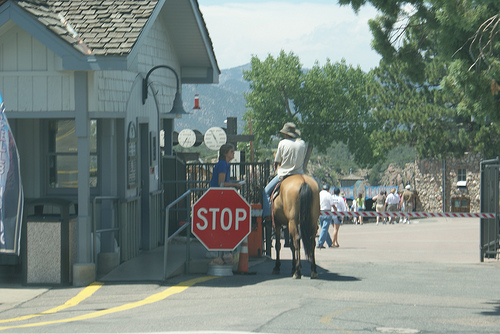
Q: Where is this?
A: This is at the road.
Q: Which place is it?
A: It is a road.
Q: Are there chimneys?
A: No, there are no chimneys.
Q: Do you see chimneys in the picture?
A: No, there are no chimneys.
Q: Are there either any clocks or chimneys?
A: No, there are no chimneys or clocks.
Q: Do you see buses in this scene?
A: No, there are no buses.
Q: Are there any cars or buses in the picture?
A: No, there are no buses or cars.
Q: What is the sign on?
A: The sign is on the pole.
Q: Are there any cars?
A: No, there are no cars.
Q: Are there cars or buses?
A: No, there are no cars or buses.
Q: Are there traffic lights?
A: No, there are no traffic lights.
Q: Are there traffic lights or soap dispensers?
A: No, there are no traffic lights or soap dispensers.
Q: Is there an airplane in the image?
A: No, there are no airplanes.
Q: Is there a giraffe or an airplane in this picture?
A: No, there are no airplanes or giraffes.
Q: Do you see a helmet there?
A: No, there are no helmets.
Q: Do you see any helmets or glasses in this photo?
A: No, there are no helmets or glasses.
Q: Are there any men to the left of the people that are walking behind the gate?
A: Yes, there is a man to the left of the people.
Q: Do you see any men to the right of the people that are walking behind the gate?
A: No, the man is to the left of the people.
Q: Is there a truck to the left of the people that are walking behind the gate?
A: No, there is a man to the left of the people.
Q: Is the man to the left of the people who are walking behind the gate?
A: Yes, the man is to the left of the people.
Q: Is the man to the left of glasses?
A: No, the man is to the left of the people.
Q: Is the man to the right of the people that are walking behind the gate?
A: No, the man is to the left of the people.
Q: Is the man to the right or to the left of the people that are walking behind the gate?
A: The man is to the left of the people.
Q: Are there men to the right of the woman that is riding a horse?
A: Yes, there is a man to the right of the woman.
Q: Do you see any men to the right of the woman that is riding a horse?
A: Yes, there is a man to the right of the woman.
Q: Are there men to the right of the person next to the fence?
A: Yes, there is a man to the right of the woman.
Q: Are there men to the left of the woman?
A: No, the man is to the right of the woman.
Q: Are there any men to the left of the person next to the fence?
A: No, the man is to the right of the woman.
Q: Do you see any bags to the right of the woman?
A: No, there is a man to the right of the woman.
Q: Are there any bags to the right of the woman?
A: No, there is a man to the right of the woman.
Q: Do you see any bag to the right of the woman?
A: No, there is a man to the right of the woman.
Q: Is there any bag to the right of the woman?
A: No, there is a man to the right of the woman.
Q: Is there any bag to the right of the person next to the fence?
A: No, there is a man to the right of the woman.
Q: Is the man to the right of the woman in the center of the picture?
A: Yes, the man is to the right of the woman.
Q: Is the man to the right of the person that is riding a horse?
A: Yes, the man is to the right of the woman.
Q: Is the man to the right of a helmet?
A: No, the man is to the right of the woman.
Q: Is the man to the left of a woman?
A: No, the man is to the right of a woman.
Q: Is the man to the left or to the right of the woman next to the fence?
A: The man is to the right of the woman.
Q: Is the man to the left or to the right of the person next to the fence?
A: The man is to the right of the woman.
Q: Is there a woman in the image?
A: Yes, there is a woman.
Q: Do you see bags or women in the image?
A: Yes, there is a woman.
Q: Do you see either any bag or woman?
A: Yes, there is a woman.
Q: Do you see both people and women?
A: Yes, there are both a woman and a person.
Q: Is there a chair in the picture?
A: No, there are no chairs.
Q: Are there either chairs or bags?
A: No, there are no chairs or bags.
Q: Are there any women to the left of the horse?
A: Yes, there is a woman to the left of the horse.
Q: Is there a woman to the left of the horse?
A: Yes, there is a woman to the left of the horse.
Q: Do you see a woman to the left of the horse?
A: Yes, there is a woman to the left of the horse.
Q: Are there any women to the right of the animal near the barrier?
A: No, the woman is to the left of the horse.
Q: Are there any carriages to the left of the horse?
A: No, there is a woman to the left of the horse.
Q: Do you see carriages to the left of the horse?
A: No, there is a woman to the left of the horse.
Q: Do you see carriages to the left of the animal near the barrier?
A: No, there is a woman to the left of the horse.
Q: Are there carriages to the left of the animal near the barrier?
A: No, there is a woman to the left of the horse.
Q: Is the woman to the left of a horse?
A: Yes, the woman is to the left of a horse.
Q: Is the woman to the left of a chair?
A: No, the woman is to the left of a horse.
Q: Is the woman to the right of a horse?
A: No, the woman is to the left of a horse.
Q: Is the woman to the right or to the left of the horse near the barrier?
A: The woman is to the left of the horse.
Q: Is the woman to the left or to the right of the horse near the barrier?
A: The woman is to the left of the horse.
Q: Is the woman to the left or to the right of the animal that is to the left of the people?
A: The woman is to the left of the horse.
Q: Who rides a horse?
A: The woman rides a horse.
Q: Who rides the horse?
A: The woman rides a horse.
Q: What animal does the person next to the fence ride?
A: The woman rides a horse.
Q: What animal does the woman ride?
A: The woman rides a horse.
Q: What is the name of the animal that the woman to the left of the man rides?
A: The animal is a horse.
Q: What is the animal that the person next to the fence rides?
A: The animal is a horse.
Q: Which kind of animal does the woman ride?
A: The woman rides a horse.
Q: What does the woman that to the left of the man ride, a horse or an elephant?
A: The woman rides a horse.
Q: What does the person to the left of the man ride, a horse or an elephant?
A: The woman rides a horse.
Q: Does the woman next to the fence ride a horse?
A: Yes, the woman rides a horse.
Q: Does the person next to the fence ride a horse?
A: Yes, the woman rides a horse.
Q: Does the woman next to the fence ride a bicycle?
A: No, the woman rides a horse.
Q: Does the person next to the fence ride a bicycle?
A: No, the woman rides a horse.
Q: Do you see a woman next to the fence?
A: Yes, there is a woman next to the fence.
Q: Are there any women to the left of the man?
A: Yes, there is a woman to the left of the man.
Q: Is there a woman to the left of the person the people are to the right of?
A: Yes, there is a woman to the left of the man.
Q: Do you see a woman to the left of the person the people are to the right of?
A: Yes, there is a woman to the left of the man.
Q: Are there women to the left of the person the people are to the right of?
A: Yes, there is a woman to the left of the man.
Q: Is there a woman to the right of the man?
A: No, the woman is to the left of the man.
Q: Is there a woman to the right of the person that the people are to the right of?
A: No, the woman is to the left of the man.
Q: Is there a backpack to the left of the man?
A: No, there is a woman to the left of the man.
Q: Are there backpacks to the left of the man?
A: No, there is a woman to the left of the man.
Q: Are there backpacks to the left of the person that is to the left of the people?
A: No, there is a woman to the left of the man.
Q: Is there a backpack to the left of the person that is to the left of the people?
A: No, there is a woman to the left of the man.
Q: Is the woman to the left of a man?
A: Yes, the woman is to the left of a man.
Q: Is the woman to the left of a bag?
A: No, the woman is to the left of a man.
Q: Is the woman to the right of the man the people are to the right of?
A: No, the woman is to the left of the man.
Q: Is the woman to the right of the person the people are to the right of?
A: No, the woman is to the left of the man.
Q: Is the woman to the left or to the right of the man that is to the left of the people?
A: The woman is to the left of the man.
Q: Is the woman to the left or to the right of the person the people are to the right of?
A: The woman is to the left of the man.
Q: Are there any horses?
A: Yes, there is a horse.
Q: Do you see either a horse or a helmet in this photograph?
A: Yes, there is a horse.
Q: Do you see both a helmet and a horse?
A: No, there is a horse but no helmets.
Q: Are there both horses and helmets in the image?
A: No, there is a horse but no helmets.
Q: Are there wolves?
A: No, there are no wolves.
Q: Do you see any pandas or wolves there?
A: No, there are no wolves or pandas.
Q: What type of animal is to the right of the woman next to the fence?
A: The animal is a horse.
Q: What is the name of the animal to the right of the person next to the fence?
A: The animal is a horse.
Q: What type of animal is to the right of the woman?
A: The animal is a horse.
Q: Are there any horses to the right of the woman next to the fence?
A: Yes, there is a horse to the right of the woman.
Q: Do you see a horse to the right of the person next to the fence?
A: Yes, there is a horse to the right of the woman.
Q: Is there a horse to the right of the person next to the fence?
A: Yes, there is a horse to the right of the woman.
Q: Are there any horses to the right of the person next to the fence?
A: Yes, there is a horse to the right of the woman.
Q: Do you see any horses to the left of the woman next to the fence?
A: No, the horse is to the right of the woman.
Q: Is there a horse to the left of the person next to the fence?
A: No, the horse is to the right of the woman.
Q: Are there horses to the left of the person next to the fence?
A: No, the horse is to the right of the woman.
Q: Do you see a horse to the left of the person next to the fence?
A: No, the horse is to the right of the woman.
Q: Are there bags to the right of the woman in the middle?
A: No, there is a horse to the right of the woman.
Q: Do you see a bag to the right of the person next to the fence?
A: No, there is a horse to the right of the woman.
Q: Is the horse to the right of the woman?
A: Yes, the horse is to the right of the woman.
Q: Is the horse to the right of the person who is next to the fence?
A: Yes, the horse is to the right of the woman.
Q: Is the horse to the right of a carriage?
A: No, the horse is to the right of the woman.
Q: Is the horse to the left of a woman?
A: No, the horse is to the right of a woman.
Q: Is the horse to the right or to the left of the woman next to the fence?
A: The horse is to the right of the woman.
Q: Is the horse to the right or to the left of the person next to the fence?
A: The horse is to the right of the woman.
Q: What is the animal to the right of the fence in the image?
A: The animal is a horse.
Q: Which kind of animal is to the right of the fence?
A: The animal is a horse.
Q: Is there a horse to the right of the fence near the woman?
A: Yes, there is a horse to the right of the fence.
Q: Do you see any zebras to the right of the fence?
A: No, there is a horse to the right of the fence.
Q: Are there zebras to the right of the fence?
A: No, there is a horse to the right of the fence.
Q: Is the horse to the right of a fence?
A: Yes, the horse is to the right of a fence.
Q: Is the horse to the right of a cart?
A: No, the horse is to the right of a fence.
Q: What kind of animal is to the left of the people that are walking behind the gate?
A: The animal is a horse.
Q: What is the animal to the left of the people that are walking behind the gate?
A: The animal is a horse.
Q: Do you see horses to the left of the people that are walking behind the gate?
A: Yes, there is a horse to the left of the people.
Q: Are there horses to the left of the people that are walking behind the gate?
A: Yes, there is a horse to the left of the people.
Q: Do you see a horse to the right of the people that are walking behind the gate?
A: No, the horse is to the left of the people.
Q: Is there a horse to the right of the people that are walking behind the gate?
A: No, the horse is to the left of the people.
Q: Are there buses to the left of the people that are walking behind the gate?
A: No, there is a horse to the left of the people.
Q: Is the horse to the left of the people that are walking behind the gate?
A: Yes, the horse is to the left of the people.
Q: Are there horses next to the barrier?
A: Yes, there is a horse next to the barrier.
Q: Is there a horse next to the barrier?
A: Yes, there is a horse next to the barrier.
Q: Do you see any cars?
A: No, there are no cars.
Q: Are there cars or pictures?
A: No, there are no cars or pictures.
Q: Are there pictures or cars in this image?
A: No, there are no cars or pictures.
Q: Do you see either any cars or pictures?
A: No, there are no cars or pictures.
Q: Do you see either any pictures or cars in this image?
A: No, there are no cars or pictures.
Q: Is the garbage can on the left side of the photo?
A: Yes, the garbage can is on the left of the image.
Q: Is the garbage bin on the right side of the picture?
A: No, the garbage bin is on the left of the image.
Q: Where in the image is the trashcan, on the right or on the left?
A: The trashcan is on the left of the image.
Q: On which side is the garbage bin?
A: The garbage bin is on the left of the image.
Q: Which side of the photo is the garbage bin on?
A: The garbage bin is on the left of the image.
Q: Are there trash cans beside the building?
A: Yes, there is a trash can beside the building.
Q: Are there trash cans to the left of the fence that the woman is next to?
A: Yes, there is a trash can to the left of the fence.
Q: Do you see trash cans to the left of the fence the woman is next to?
A: Yes, there is a trash can to the left of the fence.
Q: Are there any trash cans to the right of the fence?
A: No, the trash can is to the left of the fence.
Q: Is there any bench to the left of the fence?
A: No, there is a trash can to the left of the fence.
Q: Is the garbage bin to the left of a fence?
A: Yes, the garbage bin is to the left of a fence.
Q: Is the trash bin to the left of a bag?
A: No, the trash bin is to the left of a fence.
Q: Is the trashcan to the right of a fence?
A: No, the trashcan is to the left of a fence.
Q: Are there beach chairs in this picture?
A: No, there are no beach chairs.